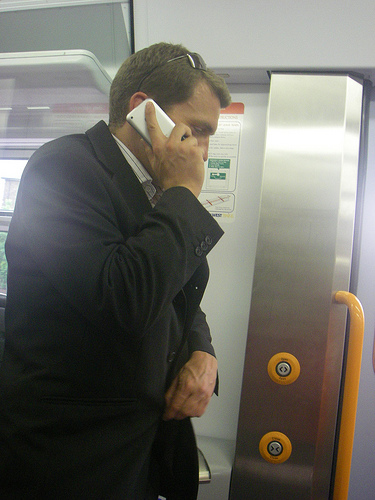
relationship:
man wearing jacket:
[8, 40, 270, 488] [17, 133, 235, 456]